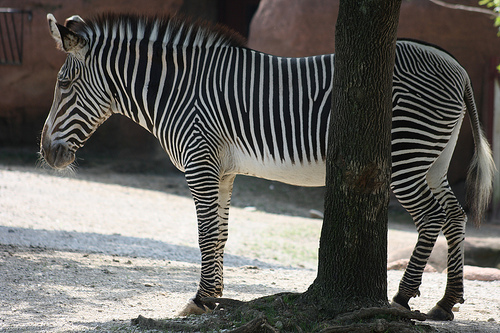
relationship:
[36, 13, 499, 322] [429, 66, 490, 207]
animal has tail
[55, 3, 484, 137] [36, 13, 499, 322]
building behind animal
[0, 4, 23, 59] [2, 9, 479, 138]
attachment to building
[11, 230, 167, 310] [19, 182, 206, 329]
shadows on ground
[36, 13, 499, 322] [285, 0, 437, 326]
animal standing by tree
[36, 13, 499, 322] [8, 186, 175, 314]
animal looking at ground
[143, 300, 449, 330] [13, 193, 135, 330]
roots on ground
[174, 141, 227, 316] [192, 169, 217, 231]
legs displaying stripes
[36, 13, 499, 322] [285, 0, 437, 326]
animal standing behind tree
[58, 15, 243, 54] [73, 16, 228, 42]
mane displaying fringed strips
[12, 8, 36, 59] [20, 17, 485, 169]
container hanging on a wall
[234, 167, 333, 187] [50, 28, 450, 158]
belly with noted absence of stripes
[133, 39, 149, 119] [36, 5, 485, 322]
stripe on animal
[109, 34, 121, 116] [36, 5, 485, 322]
stripe on animal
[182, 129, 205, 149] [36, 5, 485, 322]
stripe on animal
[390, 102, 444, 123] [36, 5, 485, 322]
stripe on animal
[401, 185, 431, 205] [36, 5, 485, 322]
stripe on animal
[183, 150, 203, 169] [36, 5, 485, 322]
strip on animal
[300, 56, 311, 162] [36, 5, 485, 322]
strip on animal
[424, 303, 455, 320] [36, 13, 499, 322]
foot of a animal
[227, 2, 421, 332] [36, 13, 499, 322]
tree front of animal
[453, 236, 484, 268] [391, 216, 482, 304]
hole in ground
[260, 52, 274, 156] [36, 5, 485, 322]
stripe on animal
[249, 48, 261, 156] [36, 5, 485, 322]
stripe on animal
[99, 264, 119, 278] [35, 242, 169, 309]
rock on ground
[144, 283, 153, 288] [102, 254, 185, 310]
rock on ground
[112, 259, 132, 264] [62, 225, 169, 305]
rock on ground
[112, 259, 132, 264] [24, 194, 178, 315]
rock on ground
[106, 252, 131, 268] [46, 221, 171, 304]
rock on ground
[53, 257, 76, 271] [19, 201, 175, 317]
rock on ground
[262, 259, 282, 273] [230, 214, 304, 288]
rock on ground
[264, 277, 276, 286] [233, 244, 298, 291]
rock on ground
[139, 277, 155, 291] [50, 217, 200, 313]
rock on ground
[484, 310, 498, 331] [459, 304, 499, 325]
rock on ground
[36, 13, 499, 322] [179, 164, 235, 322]
animal has legs